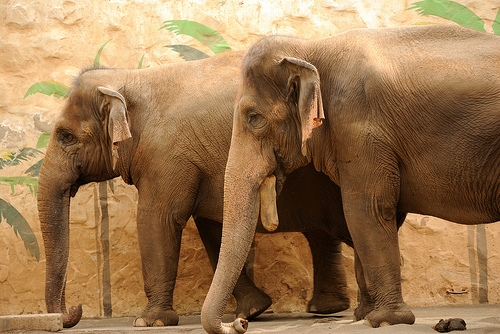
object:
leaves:
[156, 11, 235, 56]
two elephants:
[36, 19, 500, 331]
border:
[278, 52, 324, 121]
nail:
[131, 318, 148, 328]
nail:
[152, 317, 166, 327]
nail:
[362, 315, 372, 327]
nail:
[378, 320, 390, 328]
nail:
[309, 304, 317, 312]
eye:
[232, 104, 270, 138]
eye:
[49, 125, 81, 147]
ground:
[450, 116, 455, 126]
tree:
[22, 74, 72, 99]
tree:
[152, 16, 232, 61]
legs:
[299, 226, 348, 299]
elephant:
[195, 21, 500, 331]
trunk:
[200, 127, 271, 332]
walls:
[0, 0, 498, 316]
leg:
[333, 146, 407, 306]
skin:
[381, 94, 443, 142]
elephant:
[36, 51, 408, 327]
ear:
[95, 85, 132, 172]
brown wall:
[0, 0, 74, 72]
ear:
[271, 51, 329, 163]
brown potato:
[22, 24, 347, 328]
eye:
[242, 109, 267, 130]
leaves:
[0, 193, 43, 263]